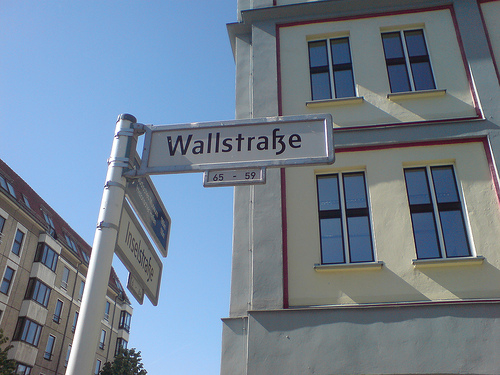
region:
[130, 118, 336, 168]
white street sign on polel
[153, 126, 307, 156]
black writing on sign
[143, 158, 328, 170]
silver boarder on sign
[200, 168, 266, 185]
black writing on sign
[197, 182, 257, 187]
silver boarder on sign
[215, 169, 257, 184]
black numbers on sign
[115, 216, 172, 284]
white sign on post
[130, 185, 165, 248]
blue sign on post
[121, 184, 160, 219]
white writing on sign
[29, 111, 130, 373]
long white sign post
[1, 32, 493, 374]
city street corner scene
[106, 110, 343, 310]
street signs on sign post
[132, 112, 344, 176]
street sign is rectangular shaped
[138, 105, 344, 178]
street sign is white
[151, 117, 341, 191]
street sign states Wallstrafze 65-69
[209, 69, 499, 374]
white and yellow building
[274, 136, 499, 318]
red trim around window section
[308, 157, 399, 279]
four panes in a window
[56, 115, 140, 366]
sign post on street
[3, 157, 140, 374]
tan building along street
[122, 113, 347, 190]
street sign on the pole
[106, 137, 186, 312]
street sign on the pole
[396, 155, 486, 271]
Window on a building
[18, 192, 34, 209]
Sun window on the roof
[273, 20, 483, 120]
red paint in the window frame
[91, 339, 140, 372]
trees in front of the building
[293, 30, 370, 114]
Window on a yellow building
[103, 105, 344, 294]
Pole with street signs on it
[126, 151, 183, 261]
Blue sign on a street pole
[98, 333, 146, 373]
Tree in front of the apartment building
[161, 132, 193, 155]
black letter on sign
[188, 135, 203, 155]
black letter on sign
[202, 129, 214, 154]
black letter on sign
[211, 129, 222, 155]
black letter on sign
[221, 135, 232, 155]
black letter on sign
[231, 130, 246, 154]
black letter on sign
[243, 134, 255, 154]
black letter on sign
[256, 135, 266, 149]
black letter on sign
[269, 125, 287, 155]
black letter on sign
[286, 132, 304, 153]
black letter on sign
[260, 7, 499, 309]
red trim around the windows of a building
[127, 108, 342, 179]
a white and black sign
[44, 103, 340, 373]
a street sign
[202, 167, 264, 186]
numbers on a street sign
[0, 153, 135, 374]
a brown building with many windows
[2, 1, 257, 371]
clear bright blue sky above the buildings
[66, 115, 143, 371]
a silver pole on the street sign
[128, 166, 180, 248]
blue and white street sign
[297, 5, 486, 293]
windows on the side of a building